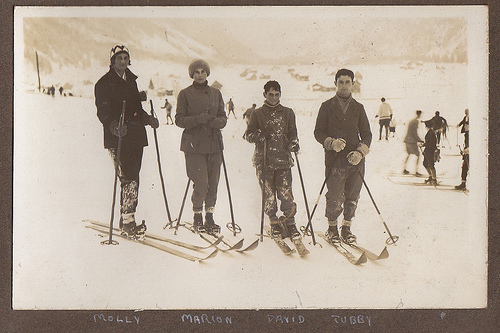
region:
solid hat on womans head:
[185, 55, 212, 75]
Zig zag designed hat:
[106, 40, 133, 55]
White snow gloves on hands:
[318, 135, 370, 161]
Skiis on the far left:
[78, 215, 226, 263]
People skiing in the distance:
[369, 91, 470, 187]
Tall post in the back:
[33, 47, 43, 92]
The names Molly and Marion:
[90, 306, 237, 328]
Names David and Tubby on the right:
[260, 310, 392, 331]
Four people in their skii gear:
[92, 40, 397, 258]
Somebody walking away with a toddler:
[373, 90, 397, 140]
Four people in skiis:
[80, 45, 400, 265]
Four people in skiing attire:
[81, 45, 400, 265]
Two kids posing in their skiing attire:
[243, 68, 398, 265]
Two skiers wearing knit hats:
[80, 43, 260, 261]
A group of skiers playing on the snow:
[386, 109, 468, 191]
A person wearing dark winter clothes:
[92, 43, 159, 235]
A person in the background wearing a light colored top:
[374, 97, 397, 141]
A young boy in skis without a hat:
[313, 68, 398, 265]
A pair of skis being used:
[313, 227, 389, 264]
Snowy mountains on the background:
[22, 15, 467, 72]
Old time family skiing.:
[74, 41, 407, 269]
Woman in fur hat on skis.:
[168, 56, 261, 258]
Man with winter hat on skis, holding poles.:
[76, 38, 223, 263]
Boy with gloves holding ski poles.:
[308, 64, 413, 269]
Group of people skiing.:
[391, 102, 472, 198]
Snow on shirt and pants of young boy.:
[242, 79, 315, 261]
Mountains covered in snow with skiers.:
[24, 14, 473, 96]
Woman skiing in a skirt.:
[391, 107, 425, 181]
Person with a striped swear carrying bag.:
[371, 95, 398, 146]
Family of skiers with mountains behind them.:
[46, 13, 451, 289]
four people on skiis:
[75, 36, 405, 271]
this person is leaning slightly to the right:
[236, 70, 321, 263]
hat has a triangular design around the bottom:
[100, 34, 132, 71]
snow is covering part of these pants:
[113, 164, 147, 241]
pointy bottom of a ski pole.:
[385, 231, 401, 251]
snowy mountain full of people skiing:
[29, 25, 469, 265]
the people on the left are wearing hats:
[72, 30, 402, 263]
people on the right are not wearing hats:
[89, 33, 400, 268]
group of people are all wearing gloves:
[67, 46, 412, 268]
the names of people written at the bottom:
[87, 304, 377, 331]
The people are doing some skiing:
[55, 25, 466, 300]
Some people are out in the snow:
[70, 31, 470, 282]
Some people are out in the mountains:
[60, 30, 430, 275]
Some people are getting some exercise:
[65, 36, 435, 296]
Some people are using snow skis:
[70, 38, 445, 284]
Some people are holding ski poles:
[60, 32, 440, 285]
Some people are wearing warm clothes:
[60, 35, 420, 273]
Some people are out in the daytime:
[71, 38, 421, 283]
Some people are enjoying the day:
[88, 30, 401, 277]